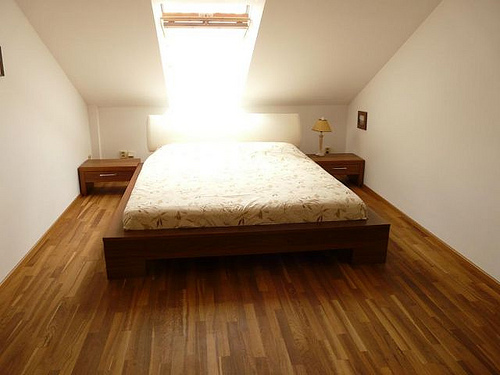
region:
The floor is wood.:
[43, 280, 478, 374]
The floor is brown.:
[50, 279, 495, 361]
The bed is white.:
[133, 104, 366, 240]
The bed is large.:
[132, 109, 360, 251]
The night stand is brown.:
[70, 144, 146, 193]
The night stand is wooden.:
[70, 141, 139, 199]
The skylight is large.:
[154, 12, 261, 125]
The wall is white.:
[393, 60, 468, 211]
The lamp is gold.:
[302, 104, 339, 161]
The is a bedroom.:
[23, 22, 487, 374]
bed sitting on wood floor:
[102, 130, 388, 285]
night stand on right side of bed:
[76, 157, 136, 197]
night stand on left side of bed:
[297, 146, 363, 191]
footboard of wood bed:
[95, 215, 386, 300]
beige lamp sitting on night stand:
[305, 115, 335, 155]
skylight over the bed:
[155, 0, 268, 80]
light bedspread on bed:
[122, 133, 368, 236]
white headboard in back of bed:
[142, 106, 297, 142]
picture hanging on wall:
[355, 110, 370, 131]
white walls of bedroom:
[3, 5, 498, 285]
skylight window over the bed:
[128, 2, 293, 189]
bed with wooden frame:
[76, 117, 397, 272]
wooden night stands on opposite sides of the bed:
[58, 105, 393, 194]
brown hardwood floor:
[0, 180, 498, 371]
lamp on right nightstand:
[306, 105, 357, 175]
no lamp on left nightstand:
[77, 137, 148, 187]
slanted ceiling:
[37, 7, 387, 192]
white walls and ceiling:
[2, 2, 498, 303]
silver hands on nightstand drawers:
[78, 159, 368, 184]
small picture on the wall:
[336, 99, 384, 151]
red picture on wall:
[353, 105, 384, 135]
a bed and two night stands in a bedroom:
[71, 114, 419, 299]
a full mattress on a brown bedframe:
[85, 140, 397, 313]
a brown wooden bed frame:
[98, 150, 392, 297]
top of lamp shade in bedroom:
[310, 120, 335, 136]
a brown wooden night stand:
[309, 145, 366, 187]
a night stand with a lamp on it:
[303, 115, 388, 186]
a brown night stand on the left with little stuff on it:
[78, 143, 145, 210]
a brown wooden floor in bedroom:
[1, 260, 494, 373]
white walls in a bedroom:
[358, 84, 498, 249]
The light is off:
[312, 97, 367, 166]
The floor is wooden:
[78, 299, 332, 359]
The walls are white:
[402, 104, 499, 218]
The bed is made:
[149, 93, 308, 300]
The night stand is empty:
[58, 139, 174, 237]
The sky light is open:
[151, 0, 275, 123]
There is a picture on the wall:
[340, 100, 394, 142]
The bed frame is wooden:
[86, 206, 475, 291]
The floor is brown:
[60, 250, 243, 366]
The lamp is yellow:
[306, 109, 353, 180]